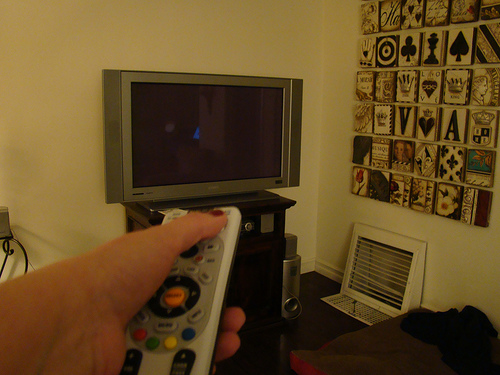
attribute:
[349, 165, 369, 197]
art — framed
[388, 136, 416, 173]
art — framed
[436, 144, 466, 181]
art — framed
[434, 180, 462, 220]
art — framed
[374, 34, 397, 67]
art — framed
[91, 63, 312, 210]
television — flat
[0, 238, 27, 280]
scroll work — iron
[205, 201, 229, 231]
nail polish — red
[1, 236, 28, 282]
wires — black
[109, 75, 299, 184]
tv — flat screen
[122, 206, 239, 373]
remote — black, silver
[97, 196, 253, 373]
controller — remote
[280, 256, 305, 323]
speaker — grey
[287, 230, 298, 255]
speaker — grey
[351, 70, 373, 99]
tiles — decorative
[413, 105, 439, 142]
tiles — decorative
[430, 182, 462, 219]
tiles — decorative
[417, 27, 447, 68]
tiles — decorative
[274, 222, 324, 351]
console — grey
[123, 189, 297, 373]
stand — tv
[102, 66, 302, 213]
tv — grey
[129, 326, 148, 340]
red button — small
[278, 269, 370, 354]
floor — hardwood, brown